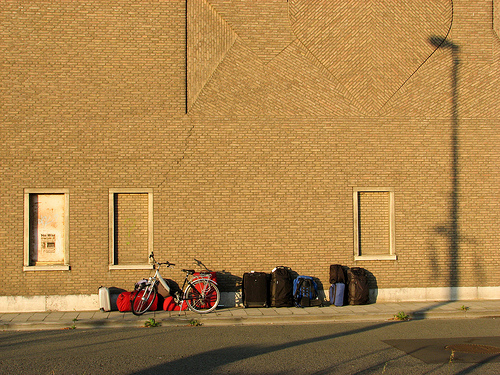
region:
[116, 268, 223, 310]
three red suitcases in a row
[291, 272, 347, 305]
two blue bags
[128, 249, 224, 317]
white and black bicycle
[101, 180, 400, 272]
two bricked over windows in a brick building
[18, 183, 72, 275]
plywood covered window in a brick building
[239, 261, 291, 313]
two black suitcases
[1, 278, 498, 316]
white stone base on a brick building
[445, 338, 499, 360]
manhole cover in a road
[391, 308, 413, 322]
tuft of vegetation growing next to the sidewalk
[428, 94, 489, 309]
utility pole shadow cast onto a brick wall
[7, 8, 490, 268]
large brown brick building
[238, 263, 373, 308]
several pieces of luggage lined up against wall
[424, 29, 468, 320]
street light shadow on brick wall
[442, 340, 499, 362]
brown manhole in the road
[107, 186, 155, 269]
brown window filled in with brick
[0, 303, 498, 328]
cement sidewalk along the road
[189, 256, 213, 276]
bicycle handle shadow on wall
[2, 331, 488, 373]
paved road that is empty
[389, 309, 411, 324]
weed growing out of crack in cement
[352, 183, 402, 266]
orange brick covered window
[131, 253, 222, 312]
white bicycle leaning on bags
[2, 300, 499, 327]
grey concrete covered sidewalk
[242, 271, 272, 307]
black suitcase on wheels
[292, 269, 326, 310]
blue and black backpack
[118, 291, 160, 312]
red rolled up sleeping bag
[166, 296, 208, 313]
red duffle style gym bag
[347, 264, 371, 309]
black rolled up sleeping bag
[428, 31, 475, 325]
shadow of street lamp pole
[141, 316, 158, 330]
weeds growing in gutter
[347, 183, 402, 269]
building window covered in brick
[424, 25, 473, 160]
shadow of street light on building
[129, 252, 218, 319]
bike parked on sidewalk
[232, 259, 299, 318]
black luggage on sidewalk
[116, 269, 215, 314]
red bags behind bike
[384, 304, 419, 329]
weed growing next to curb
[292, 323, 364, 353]
shadow of pole on street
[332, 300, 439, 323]
sidewalk between building and street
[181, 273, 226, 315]
back tire of bike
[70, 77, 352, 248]
Gray brick wall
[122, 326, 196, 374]
Gray paved street by a sidewalk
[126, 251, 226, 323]
White bike on a sidewalk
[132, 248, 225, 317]
White bike parked by a building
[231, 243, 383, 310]
Suitcases by a building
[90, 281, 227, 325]
Bags by a building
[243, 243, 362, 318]
Black and blue suitcases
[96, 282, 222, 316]
Red and black suitcases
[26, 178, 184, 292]
Windows on a building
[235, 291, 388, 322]
Gray paved sidewalk